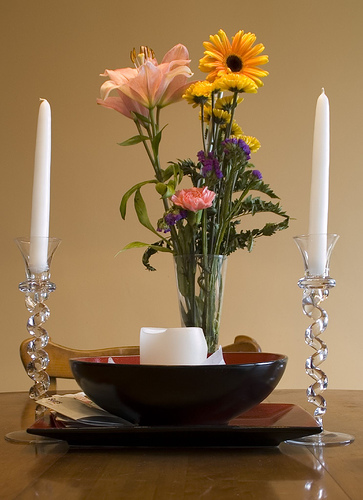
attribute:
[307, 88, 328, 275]
candle — white, thick, tall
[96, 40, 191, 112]
lily — pale pink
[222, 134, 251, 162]
flower — purple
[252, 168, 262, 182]
flower — purple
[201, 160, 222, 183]
flower — purple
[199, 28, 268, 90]
daisy — yellow, large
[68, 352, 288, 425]
bowl — dark, large, brown, black, red, lacquered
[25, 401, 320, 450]
plate — square, red, black, lacquered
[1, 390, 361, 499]
table — polished, wood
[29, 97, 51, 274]
candle — white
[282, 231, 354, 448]
candle holder — glass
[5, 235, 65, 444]
candle holder — glass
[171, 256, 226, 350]
vase — clear, glass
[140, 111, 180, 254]
stem — green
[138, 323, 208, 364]
candle — white, wide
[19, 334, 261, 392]
chair — wood